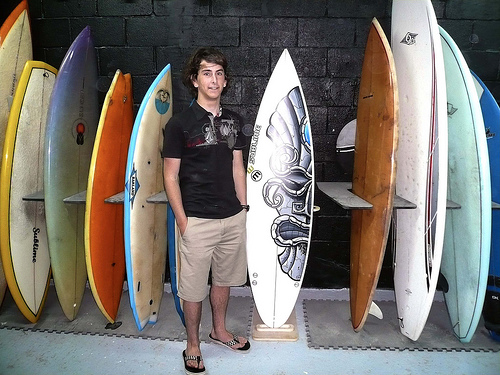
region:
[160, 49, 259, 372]
a man standing among the surfboards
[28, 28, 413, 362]
a man standing among the surfboards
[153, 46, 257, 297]
man's hands in the pocket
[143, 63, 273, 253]
man's shirt is black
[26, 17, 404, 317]
A young man and a bunch of surfboards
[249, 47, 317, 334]
This surfboard is white with a black and gray tiki god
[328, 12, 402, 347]
This surfboard is not painted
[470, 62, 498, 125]
This board is blue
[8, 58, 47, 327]
This board is yellow and white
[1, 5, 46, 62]
This is an orange and white surf board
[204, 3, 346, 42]
This wall is made of cinder blocks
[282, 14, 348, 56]
The blocks are painted black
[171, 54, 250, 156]
The boy is wearing a black shirt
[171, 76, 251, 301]
The boys wearing tan colored shorts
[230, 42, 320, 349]
THIS SURFBOARD IS WHITE WITH AN AIRBRUSHED PICTURE ON IT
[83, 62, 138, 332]
THIS SURFBOARD IS ORANGE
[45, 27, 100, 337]
THIS SURFBOARD IS BLUE GREEN AND BEIGE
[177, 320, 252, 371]
THIS GUY IS WEARING FLIP FLOPS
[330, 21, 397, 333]
THIS SURF BOARD IS BROWN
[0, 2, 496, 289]
THIS WALL IS BLACK BRICKS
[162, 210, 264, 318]
THIS GUY IS WEARING KHAKI SHORTS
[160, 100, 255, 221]
THIS GUY IS WEARING A SHORT SLEEVED, BLACK SHIRT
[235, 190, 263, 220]
THIS GUY IS WEARING A WATCH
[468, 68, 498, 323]
THIS SURFBOARD IS BLUE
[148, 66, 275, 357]
This is a man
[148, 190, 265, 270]
This is a pair of shorts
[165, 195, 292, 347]
The shorts are khaki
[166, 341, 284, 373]
These are flip flops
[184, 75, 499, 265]
These are surf boards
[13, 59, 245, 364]
These are colorful boards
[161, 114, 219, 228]
This is a black shirt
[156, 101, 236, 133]
This is a collared shirt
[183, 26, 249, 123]
The hair is short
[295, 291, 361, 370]
This is a grey mat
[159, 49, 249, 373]
a young man with hands in his pockets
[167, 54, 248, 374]
a young guy with hands in his pockets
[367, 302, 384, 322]
a fin on the bottom of a surfboard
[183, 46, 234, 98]
a head with a lot of hair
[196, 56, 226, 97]
a face with a bit of a smile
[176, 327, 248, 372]
a pair of flip flops on his feet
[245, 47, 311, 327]
a decorated surface of a surfboard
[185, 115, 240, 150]
some markings on the shirt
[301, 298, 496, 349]
a rubber mat on the floor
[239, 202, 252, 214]
a watch on the left wrist